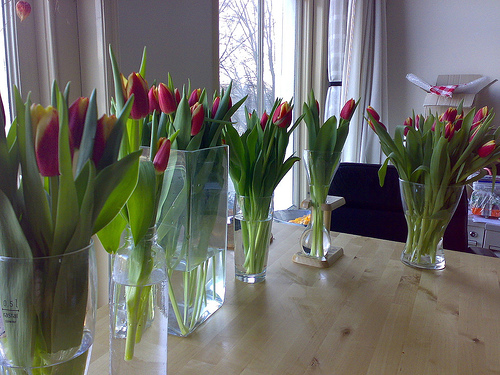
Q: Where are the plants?
A: In vases.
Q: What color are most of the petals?
A: Pink.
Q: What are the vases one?
A: A table.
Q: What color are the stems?
A: Green.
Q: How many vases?
A: Six.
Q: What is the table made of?
A: Wood.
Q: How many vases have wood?
A: One.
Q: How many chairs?
A: One.